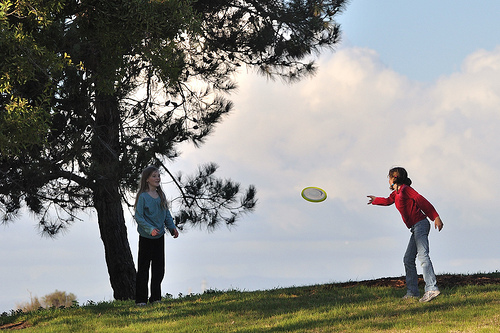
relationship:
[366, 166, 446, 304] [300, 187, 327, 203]
girl threw frisbee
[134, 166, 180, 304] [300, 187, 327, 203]
girl catching frisbee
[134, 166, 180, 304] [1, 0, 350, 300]
girl under tree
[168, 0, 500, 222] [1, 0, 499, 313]
cloud in sky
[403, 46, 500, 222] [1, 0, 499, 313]
cloud in sky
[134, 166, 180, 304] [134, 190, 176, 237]
girl wearing shirt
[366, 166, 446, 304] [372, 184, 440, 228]
girl wearing shirt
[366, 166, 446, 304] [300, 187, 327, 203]
girl playing frisbee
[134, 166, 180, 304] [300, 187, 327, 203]
girl playing frisbee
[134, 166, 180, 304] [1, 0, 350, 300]
girl next to tree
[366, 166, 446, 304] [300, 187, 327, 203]
girl throwing frisbee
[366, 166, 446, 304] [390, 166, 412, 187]
girl has hair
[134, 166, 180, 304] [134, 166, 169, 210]
girl has hair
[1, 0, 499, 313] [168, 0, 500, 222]
sky has cloud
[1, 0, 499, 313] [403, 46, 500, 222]
sky has cloud